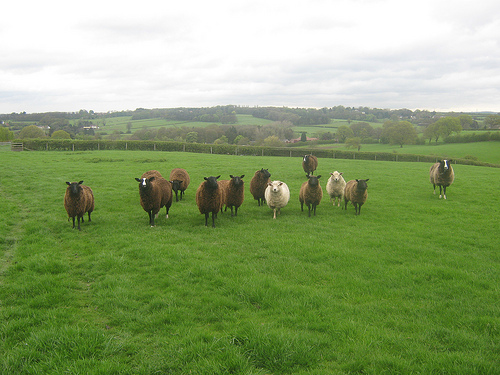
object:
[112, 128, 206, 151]
shrubs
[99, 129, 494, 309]
pastre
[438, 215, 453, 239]
ground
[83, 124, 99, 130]
building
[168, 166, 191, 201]
sheep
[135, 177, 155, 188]
face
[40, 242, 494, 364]
pasture area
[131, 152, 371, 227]
flock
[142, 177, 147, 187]
stripe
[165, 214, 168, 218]
hoof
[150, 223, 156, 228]
hoof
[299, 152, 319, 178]
sheep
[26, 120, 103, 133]
house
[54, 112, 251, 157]
hedges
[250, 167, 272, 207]
sheep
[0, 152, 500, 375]
grass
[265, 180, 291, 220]
sheep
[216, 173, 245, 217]
sheep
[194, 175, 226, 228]
sheep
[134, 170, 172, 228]
sheep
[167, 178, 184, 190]
heads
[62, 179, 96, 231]
sheep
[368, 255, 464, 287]
green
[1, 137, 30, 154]
wooden gate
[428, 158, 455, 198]
sheep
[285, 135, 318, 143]
house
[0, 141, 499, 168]
fence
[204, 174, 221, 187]
face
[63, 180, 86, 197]
head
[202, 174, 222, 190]
head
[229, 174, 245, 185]
head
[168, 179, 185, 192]
head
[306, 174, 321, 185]
head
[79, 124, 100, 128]
roof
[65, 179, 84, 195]
face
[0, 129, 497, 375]
field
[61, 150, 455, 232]
herd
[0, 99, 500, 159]
distance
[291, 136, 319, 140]
roof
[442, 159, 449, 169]
stripe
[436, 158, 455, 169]
face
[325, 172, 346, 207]
sheep